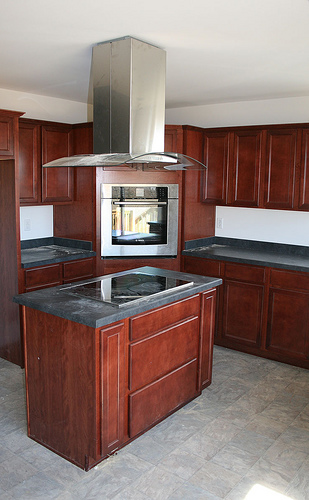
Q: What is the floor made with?
A: Tiles.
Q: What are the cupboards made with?
A: Wood.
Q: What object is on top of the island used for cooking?
A: Stove.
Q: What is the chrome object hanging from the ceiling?
A: Hood.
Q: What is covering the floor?
A: Tiles.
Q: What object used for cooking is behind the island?
A: Oven.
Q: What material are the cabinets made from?
A: Wood.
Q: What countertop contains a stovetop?
A: Island.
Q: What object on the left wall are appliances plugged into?
A: Receptacle.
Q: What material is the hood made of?
A: Stainless steel.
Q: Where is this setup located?
A: Kitchen.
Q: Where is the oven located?
A: Wall.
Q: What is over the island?
A: Vent.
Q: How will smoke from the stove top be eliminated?
A: Vent.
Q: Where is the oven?
A: In the cabinet.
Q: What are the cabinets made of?
A: Wood.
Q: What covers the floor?
A: Tile.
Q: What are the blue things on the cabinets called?
A: Countertops.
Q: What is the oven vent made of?
A: Stainless steel.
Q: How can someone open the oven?
A: Handle.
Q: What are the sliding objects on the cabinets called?
A: Drawers.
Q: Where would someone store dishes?
A: Top cabinets.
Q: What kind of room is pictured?
A: A kitchen.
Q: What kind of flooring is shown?
A: Tiles.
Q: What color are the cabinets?
A: Dark red wood.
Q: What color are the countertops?
A: Black.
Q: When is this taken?
A: During the day.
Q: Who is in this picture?
A: No one.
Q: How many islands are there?
A: One.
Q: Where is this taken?
A: In a kitchen.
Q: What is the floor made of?
A: Tile.